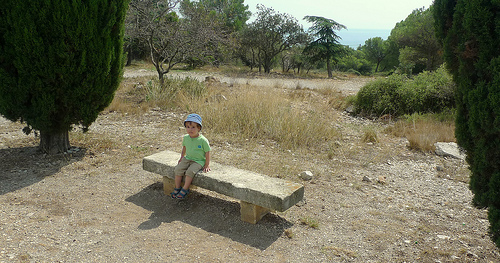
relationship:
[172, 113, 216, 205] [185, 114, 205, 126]
person wearing hat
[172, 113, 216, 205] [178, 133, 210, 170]
person wearing shirt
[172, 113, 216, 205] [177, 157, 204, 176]
person wearing short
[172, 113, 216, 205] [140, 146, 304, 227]
person sitting on park bench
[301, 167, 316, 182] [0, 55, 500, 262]
rock on ground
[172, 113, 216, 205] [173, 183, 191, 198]
person has sandal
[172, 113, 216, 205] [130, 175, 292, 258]
person has shadow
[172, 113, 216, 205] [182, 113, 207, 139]
person has head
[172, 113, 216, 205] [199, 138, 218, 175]
person has arm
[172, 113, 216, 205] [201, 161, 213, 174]
person has hand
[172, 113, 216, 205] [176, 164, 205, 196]
person has leg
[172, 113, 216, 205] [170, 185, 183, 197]
person has foot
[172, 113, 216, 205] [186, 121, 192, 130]
person has eye